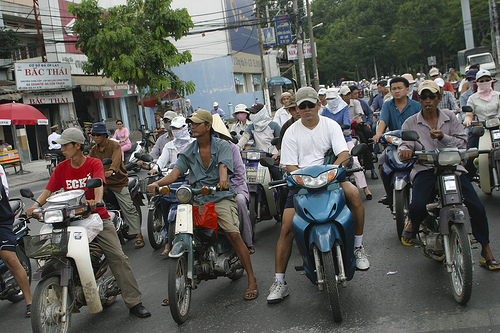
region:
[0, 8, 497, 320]
Large amount of motorcycle riders on street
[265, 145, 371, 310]
Turquoise blue motorcycle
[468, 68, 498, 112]
Rider with pink cloth over face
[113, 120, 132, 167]
Rider wearing all pink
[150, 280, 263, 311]
Motorcycle rider with sandles on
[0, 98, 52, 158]
Large red umbrella on sidewalk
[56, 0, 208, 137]
Tree on sidewalk area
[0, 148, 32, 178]
Multicolored bench on sidewalk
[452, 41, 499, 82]
White truck with black and tan back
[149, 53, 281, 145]
Powder blue building in backgroun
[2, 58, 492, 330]
many riders on motorscooters and motorcycles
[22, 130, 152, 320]
scooter rider with tan pants, red shirt and tan cap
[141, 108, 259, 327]
scooter rider with tan shorts, blue shirt and tan hat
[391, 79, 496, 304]
scooter rider with black pants, light shirt and tan cap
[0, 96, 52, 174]
red umbrella on the sidewalk area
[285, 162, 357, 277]
blue front of a motorscooter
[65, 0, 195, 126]
green tree on the sidewalk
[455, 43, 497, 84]
white and black truck in the background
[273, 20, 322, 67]
blue and white signs mounted on poles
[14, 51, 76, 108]
white advertising signs on a building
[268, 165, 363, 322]
Blue motorbike being rode on by man white shirt.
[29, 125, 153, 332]
Man in red shirt on white motorbike.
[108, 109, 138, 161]
Woman in pink pants and pink shirt.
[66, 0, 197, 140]
Tree in front of buildings.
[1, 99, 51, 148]
Red umbrella on sidewalk.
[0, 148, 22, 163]
Yellow box with blue and red stripes.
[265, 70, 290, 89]
Blue umbrella near white wall of building.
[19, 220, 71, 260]
Black basket on front of white motorbike.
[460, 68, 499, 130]
Person wearing white hat, sunglasses and pink cloth over face.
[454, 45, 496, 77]
White truck in front of pole.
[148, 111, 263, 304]
person sitting on bike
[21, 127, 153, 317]
person sitting on bike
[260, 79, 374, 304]
person sitting on bike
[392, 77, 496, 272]
person sitting on bike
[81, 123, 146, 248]
person sitting on bike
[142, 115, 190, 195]
person sitting on bike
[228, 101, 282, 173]
person sitting on bike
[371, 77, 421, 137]
person sitting on bike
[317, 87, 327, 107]
person sitting on bike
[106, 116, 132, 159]
person sitting on bike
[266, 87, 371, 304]
man sitting on the blue motor bike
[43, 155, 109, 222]
red shirt young boy is wearing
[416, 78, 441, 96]
khaki cap man is wearing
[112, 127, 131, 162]
pink outfit woman is wearing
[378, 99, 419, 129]
man in dark blue shirt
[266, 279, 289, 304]
white tennis shoe on man's right foot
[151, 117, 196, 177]
person dressed in all white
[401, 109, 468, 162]
man wearing lavender shirt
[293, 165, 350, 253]
blue part of motor bike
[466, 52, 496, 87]
white truck in the background